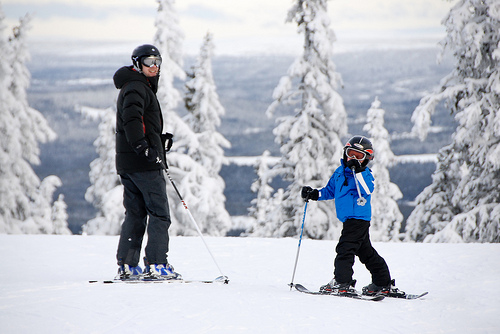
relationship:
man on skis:
[113, 44, 184, 283] [85, 272, 230, 287]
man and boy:
[113, 44, 184, 283] [302, 136, 395, 297]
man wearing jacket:
[113, 44, 184, 283] [112, 65, 170, 174]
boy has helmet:
[302, 136, 395, 297] [342, 134, 374, 163]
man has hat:
[113, 44, 184, 283] [129, 44, 161, 66]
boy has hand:
[302, 136, 395, 297] [347, 159, 361, 172]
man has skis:
[113, 44, 184, 283] [85, 272, 230, 287]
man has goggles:
[113, 44, 184, 283] [140, 55, 164, 69]